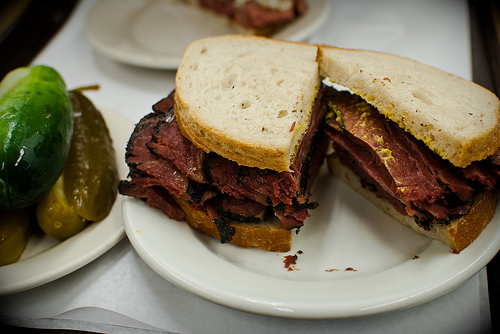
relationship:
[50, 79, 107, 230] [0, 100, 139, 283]
pickle on plate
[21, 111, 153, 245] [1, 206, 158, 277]
pickle on plate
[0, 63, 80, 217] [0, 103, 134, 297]
pickle on plate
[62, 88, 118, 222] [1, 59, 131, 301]
pickle on plate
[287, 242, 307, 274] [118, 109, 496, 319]
sauce on plate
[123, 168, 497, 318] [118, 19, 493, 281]
plate holding sandwich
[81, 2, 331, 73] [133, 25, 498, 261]
plate behind sandwich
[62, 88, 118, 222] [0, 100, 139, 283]
pickle on plate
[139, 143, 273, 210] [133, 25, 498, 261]
meat inside sandwich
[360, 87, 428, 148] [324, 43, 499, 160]
mustard on bread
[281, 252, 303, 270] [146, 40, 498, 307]
meat crumb on plate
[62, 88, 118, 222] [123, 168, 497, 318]
pickle on plate